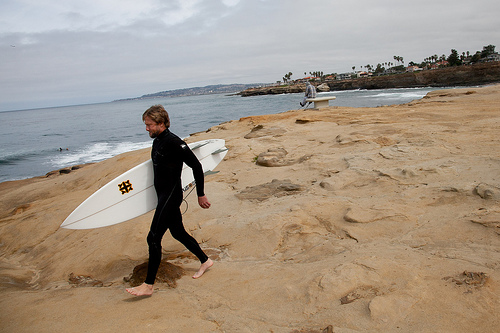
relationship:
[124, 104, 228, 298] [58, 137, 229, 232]
man carrying surfboard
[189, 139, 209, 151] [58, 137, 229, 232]
fin on surfboard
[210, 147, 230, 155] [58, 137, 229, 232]
fin on surfboard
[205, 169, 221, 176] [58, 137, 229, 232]
fin on surfboard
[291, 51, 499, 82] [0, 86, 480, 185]
buildings on coast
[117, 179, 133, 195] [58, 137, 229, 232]
logo on surfboard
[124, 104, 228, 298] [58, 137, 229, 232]
man holding surfboard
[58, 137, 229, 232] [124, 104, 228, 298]
surfboard next to man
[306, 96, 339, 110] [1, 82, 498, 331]
bench on ground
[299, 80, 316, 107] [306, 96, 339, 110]
jumper on bench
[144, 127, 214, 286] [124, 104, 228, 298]
swimsuit on man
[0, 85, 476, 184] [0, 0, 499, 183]
water in background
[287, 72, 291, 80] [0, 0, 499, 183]
tree in background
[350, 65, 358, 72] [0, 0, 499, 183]
tree in background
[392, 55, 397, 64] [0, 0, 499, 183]
tree in background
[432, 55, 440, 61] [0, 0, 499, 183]
tree in background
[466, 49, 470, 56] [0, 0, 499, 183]
tree in background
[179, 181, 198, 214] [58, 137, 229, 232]
cord on surfboard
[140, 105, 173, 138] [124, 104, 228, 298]
head on man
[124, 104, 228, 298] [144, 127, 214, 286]
man in swimsuit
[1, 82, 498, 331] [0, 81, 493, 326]
sand covering beach